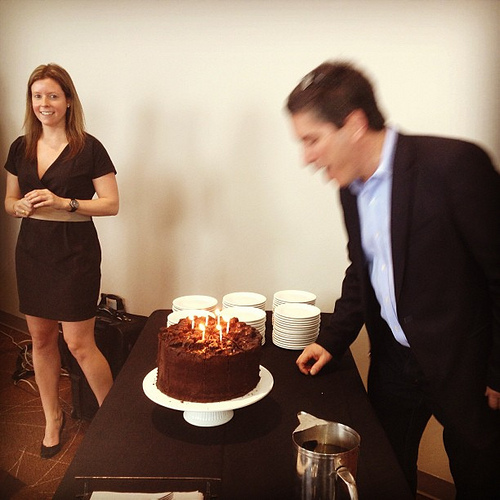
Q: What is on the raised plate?
A: A cake.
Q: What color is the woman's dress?
A: Black.